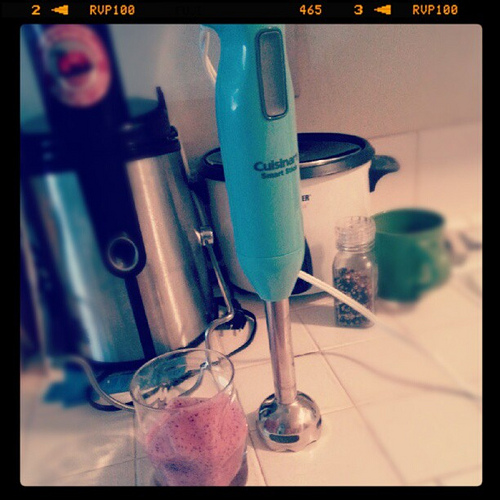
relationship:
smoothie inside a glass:
[132, 348, 253, 488] [131, 345, 253, 488]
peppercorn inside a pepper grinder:
[344, 275, 352, 283] [330, 209, 382, 331]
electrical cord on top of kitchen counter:
[299, 268, 482, 408] [21, 214, 483, 488]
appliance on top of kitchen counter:
[198, 131, 400, 298] [21, 214, 483, 488]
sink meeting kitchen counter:
[418, 219, 482, 309] [21, 214, 483, 488]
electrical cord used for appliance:
[299, 268, 482, 408] [198, 131, 400, 298]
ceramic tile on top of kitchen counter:
[248, 406, 406, 487] [21, 214, 483, 488]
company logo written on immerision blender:
[250, 153, 300, 173] [196, 24, 326, 455]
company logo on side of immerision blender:
[250, 153, 300, 173] [196, 24, 326, 455]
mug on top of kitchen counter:
[372, 207, 455, 304] [21, 214, 483, 488]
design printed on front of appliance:
[32, 23, 114, 109] [18, 85, 237, 376]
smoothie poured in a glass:
[132, 348, 253, 488] [131, 345, 253, 488]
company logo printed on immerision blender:
[250, 153, 300, 173] [196, 24, 326, 455]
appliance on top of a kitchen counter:
[198, 131, 400, 298] [21, 214, 483, 488]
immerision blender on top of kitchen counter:
[196, 24, 326, 455] [21, 214, 483, 488]